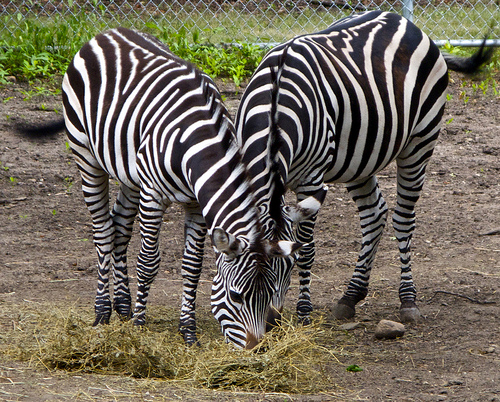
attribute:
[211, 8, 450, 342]
zebra — black, white, striped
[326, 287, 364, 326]
hoof — gray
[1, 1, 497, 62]
fence — silver, chain link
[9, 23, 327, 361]
zebra — black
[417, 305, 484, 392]
dirt — limbs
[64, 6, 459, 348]
zebras — eating, couple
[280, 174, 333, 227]
ear — black, white, zebras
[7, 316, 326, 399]
hay — light brown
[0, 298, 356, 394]
grass — dry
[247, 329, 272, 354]
nose — brown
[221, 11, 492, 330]
zebra — eating 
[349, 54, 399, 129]
strips — black , white 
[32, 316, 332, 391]
hay — yellow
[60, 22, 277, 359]
zebra — white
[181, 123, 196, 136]
stripes — black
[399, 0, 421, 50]
fence — metal, vertical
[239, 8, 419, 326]
zebras — white, black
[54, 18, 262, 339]
zebras — white, black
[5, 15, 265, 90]
grass — green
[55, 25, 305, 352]
zebra — eating 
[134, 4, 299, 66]
metal fence — silver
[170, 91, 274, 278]
neck — zebras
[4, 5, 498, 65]
fence — chain link